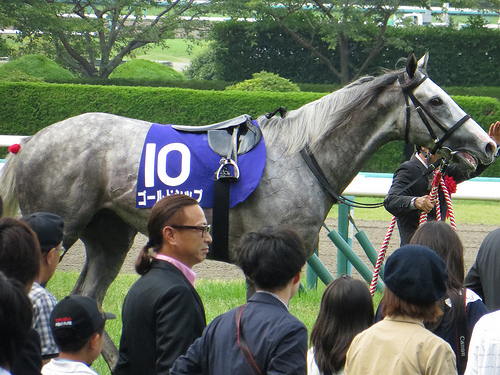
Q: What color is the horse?
A: Grey.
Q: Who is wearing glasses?
A: Two men.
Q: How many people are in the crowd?
A: Eleven.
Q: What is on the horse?
A: A saddle.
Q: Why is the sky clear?
A: The weather is clear.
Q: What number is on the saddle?
A: Ten.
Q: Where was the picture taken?
A: At the horse track.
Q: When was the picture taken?
A: In the daytime.